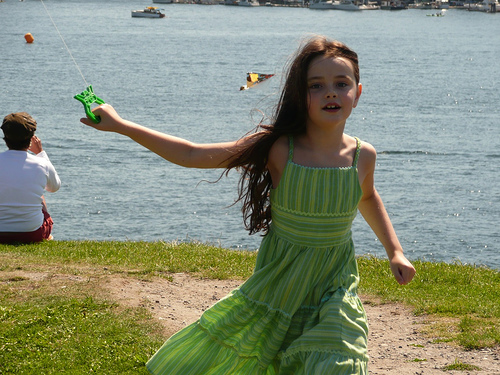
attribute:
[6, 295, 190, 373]
grass — green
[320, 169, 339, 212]
stripe — yellow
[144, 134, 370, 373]
dress — yellow, stripe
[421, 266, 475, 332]
grass — green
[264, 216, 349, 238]
stripe — yellow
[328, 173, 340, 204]
stripe — yellow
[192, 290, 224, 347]
stripe — yellow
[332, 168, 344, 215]
stripe — yellow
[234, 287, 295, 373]
stripe — yellow